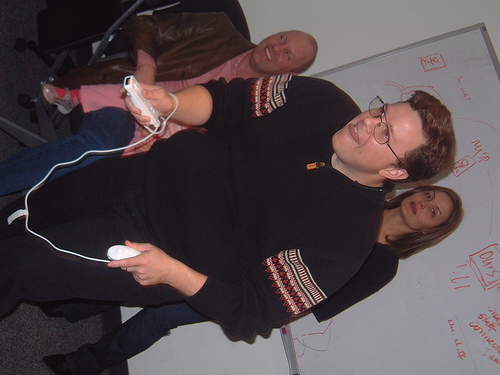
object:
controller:
[125, 77, 163, 127]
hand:
[118, 82, 170, 129]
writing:
[469, 139, 492, 164]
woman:
[315, 183, 462, 316]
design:
[263, 248, 330, 314]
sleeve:
[185, 251, 348, 332]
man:
[0, 9, 329, 185]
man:
[0, 77, 455, 342]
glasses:
[368, 95, 400, 162]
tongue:
[348, 123, 358, 142]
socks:
[53, 87, 79, 105]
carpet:
[2, 54, 29, 126]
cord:
[29, 228, 74, 253]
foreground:
[153, 127, 229, 251]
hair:
[397, 91, 456, 182]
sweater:
[117, 68, 375, 348]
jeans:
[0, 148, 150, 312]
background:
[433, 249, 496, 324]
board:
[351, 330, 381, 370]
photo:
[0, 0, 500, 375]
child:
[37, 80, 212, 148]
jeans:
[59, 299, 194, 375]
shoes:
[42, 345, 113, 375]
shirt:
[307, 235, 397, 324]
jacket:
[55, 12, 262, 89]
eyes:
[431, 209, 435, 216]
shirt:
[152, 51, 248, 94]